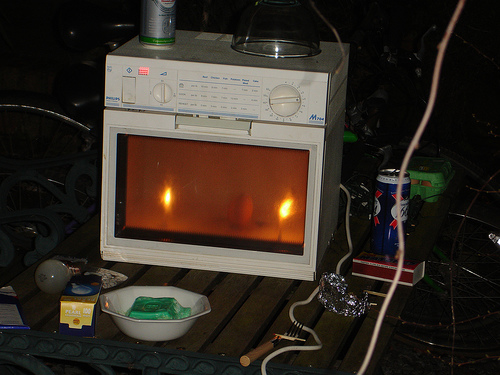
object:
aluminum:
[318, 273, 370, 317]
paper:
[3, 283, 37, 332]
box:
[401, 169, 445, 206]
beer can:
[371, 170, 411, 265]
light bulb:
[33, 256, 80, 290]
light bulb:
[30, 262, 76, 297]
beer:
[139, 0, 177, 50]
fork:
[239, 318, 304, 365]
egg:
[225, 196, 254, 225]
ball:
[315, 270, 368, 318]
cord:
[262, 0, 465, 375]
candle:
[277, 196, 295, 243]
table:
[0, 0, 500, 375]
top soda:
[380, 169, 410, 179]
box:
[349, 252, 425, 287]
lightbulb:
[36, 255, 85, 289]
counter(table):
[0, 152, 500, 374]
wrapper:
[1, 299, 25, 332]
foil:
[316, 272, 371, 317]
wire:
[400, 71, 441, 168]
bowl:
[98, 285, 211, 341]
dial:
[268, 85, 301, 117]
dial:
[152, 81, 173, 101]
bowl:
[230, 2, 322, 58]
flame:
[159, 184, 176, 209]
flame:
[279, 194, 295, 218]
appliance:
[99, 28, 348, 281]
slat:
[326, 254, 416, 371]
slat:
[79, 260, 182, 340]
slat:
[221, 270, 255, 351]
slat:
[0, 272, 23, 354]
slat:
[15, 232, 111, 261]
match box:
[348, 252, 427, 293]